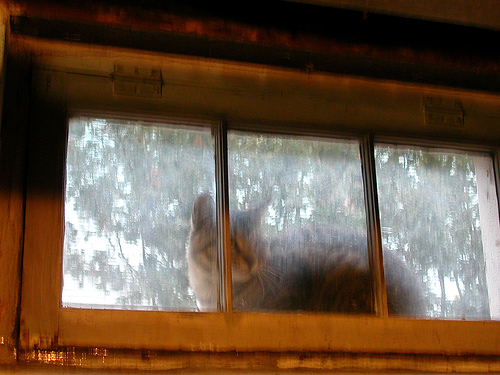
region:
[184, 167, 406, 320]
cat sitting near window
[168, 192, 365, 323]
cat is grey and white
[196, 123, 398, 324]
window has wood dividers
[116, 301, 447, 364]
window has brown border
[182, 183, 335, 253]
cat has grey ears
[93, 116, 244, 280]
green tree behind cat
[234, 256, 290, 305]
cat has white whiskers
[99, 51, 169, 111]
metal hinge on window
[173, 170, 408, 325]
cat looks in window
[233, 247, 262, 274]
cat has dark nose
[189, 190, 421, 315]
the cat outside the window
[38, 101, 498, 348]
the three window panes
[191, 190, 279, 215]
the cat's ears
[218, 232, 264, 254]
the cat's eyes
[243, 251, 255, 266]
the cat's nose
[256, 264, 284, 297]
the cat's whiskers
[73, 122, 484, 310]
the trees behind the cat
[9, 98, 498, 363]
the small closed window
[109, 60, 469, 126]
the hinges on the window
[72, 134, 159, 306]
the sky behind the trees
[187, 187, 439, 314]
Cat looking through window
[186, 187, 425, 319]
Cat sitting on the windowsill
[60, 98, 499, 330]
Window with three glass panes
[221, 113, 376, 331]
Glass pane in window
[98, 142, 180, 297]
Leaves on a tree in the background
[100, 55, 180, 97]
Hinge used to open window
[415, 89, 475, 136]
Hinge used to secure window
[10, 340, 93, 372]
Reflection of light on window frame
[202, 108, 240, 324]
Divider between window panes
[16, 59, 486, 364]
Window in the closed position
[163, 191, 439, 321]
cat outside the window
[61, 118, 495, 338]
three windows in a row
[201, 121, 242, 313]
thin rod separating the windows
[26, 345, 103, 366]
goop on the wall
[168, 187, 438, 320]
cat looking in the window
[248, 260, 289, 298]
long white whiskers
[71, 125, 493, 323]
thick green tree tops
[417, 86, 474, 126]
small silver rivet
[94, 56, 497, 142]
two small rivets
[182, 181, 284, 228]
two ears sticking out of the head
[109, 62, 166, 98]
Hinge on the inside of a window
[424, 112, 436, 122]
Screw in a hinge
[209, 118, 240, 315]
Wooden window divider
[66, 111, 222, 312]
Glass pane in a window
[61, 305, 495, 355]
Wooden window frame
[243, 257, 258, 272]
Nose on a cat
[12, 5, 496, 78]
Dark wood on a ceiling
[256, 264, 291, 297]
Whiskers in front of a cat's body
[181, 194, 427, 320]
Cat on the ground looking in a window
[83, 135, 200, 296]
Tree's behind a cat outside